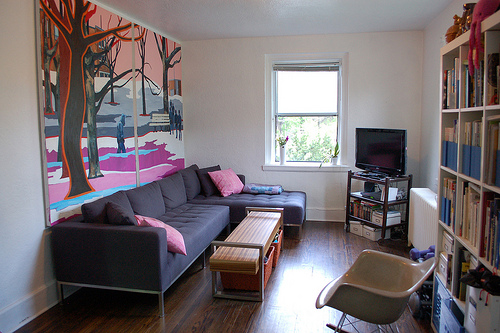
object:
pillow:
[208, 166, 245, 197]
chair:
[314, 240, 441, 325]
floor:
[15, 221, 435, 332]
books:
[432, 54, 500, 331]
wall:
[182, 35, 422, 223]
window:
[274, 68, 339, 163]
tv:
[356, 127, 406, 174]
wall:
[0, 0, 185, 332]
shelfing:
[344, 170, 412, 244]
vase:
[280, 145, 287, 163]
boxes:
[221, 222, 282, 268]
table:
[211, 206, 285, 304]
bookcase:
[430, 11, 499, 332]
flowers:
[278, 137, 289, 146]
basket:
[217, 247, 274, 291]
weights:
[408, 246, 434, 261]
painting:
[34, 1, 188, 228]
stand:
[344, 170, 412, 241]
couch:
[50, 164, 308, 318]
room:
[2, 2, 498, 332]